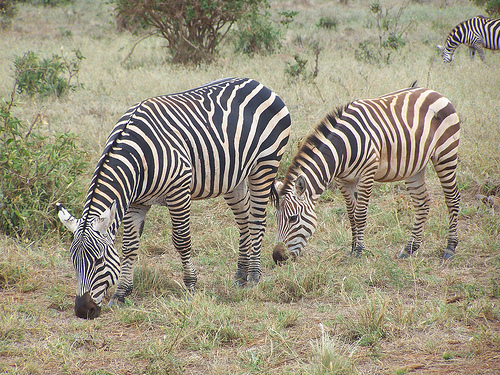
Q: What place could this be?
A: It is a field.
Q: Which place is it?
A: It is a field.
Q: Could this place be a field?
A: Yes, it is a field.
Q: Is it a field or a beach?
A: It is a field.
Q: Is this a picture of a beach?
A: No, the picture is showing a field.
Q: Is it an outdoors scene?
A: Yes, it is outdoors.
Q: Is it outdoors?
A: Yes, it is outdoors.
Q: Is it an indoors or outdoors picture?
A: It is outdoors.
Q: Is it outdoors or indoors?
A: It is outdoors.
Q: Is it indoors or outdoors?
A: It is outdoors.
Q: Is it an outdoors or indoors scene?
A: It is outdoors.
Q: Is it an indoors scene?
A: No, it is outdoors.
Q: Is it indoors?
A: No, it is outdoors.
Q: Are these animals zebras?
A: Yes, all the animals are zebras.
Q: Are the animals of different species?
A: No, all the animals are zebras.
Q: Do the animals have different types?
A: No, all the animals are zebras.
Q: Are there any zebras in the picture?
A: Yes, there are zebras.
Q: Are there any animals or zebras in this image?
A: Yes, there are zebras.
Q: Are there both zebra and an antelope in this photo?
A: No, there are zebras but no antelopes.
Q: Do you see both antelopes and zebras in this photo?
A: No, there are zebras but no antelopes.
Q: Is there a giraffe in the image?
A: No, there are no giraffes.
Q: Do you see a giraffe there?
A: No, there are no giraffes.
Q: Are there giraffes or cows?
A: No, there are no giraffes or cows.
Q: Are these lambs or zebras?
A: These are zebras.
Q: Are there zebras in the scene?
A: Yes, there is a zebra.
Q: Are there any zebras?
A: Yes, there is a zebra.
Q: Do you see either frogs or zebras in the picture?
A: Yes, there is a zebra.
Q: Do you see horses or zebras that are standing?
A: Yes, the zebra is standing.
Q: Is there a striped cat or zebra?
A: Yes, there is a striped zebra.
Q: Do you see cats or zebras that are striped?
A: Yes, the zebra is striped.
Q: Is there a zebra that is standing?
A: Yes, there is a zebra that is standing.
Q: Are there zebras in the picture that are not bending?
A: Yes, there is a zebra that is standing.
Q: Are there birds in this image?
A: No, there are no birds.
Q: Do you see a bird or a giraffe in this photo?
A: No, there are no birds or giraffes.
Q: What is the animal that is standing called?
A: The animal is a zebra.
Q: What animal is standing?
A: The animal is a zebra.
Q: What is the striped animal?
A: The animal is a zebra.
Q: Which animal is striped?
A: The animal is a zebra.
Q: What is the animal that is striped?
A: The animal is a zebra.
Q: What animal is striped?
A: The animal is a zebra.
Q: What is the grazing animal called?
A: The animal is a zebra.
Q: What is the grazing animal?
A: The animal is a zebra.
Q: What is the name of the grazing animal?
A: The animal is a zebra.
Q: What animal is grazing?
A: The animal is a zebra.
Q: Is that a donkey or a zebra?
A: That is a zebra.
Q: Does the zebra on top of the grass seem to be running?
A: No, the zebra is standing.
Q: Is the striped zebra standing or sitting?
A: The zebra is standing.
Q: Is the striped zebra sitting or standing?
A: The zebra is standing.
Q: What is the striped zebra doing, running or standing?
A: The zebra is standing.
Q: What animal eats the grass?
A: The animal is a zebra.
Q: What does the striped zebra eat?
A: The zebra eats grass.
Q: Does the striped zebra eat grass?
A: Yes, the zebra eats grass.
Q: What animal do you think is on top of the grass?
A: The zebra is on top of the grass.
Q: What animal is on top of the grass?
A: The zebra is on top of the grass.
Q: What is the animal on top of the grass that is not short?
A: The animal is a zebra.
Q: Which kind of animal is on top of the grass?
A: The animal is a zebra.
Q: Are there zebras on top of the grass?
A: Yes, there is a zebra on top of the grass.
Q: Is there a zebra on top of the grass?
A: Yes, there is a zebra on top of the grass.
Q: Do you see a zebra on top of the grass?
A: Yes, there is a zebra on top of the grass.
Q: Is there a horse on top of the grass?
A: No, there is a zebra on top of the grass.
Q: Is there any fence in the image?
A: No, there are no fences.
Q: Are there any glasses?
A: No, there are no glasses.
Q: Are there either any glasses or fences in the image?
A: No, there are no glasses or fences.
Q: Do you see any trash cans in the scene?
A: No, there are no trash cans.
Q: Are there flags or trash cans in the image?
A: No, there are no trash cans or flags.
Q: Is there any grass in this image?
A: Yes, there is grass.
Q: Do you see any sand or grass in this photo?
A: Yes, there is grass.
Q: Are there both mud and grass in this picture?
A: No, there is grass but no mud.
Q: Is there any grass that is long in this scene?
A: Yes, there is long grass.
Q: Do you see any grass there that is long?
A: Yes, there is grass that is long.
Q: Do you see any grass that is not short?
A: Yes, there is long grass.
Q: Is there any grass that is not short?
A: Yes, there is long grass.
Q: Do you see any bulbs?
A: No, there are no bulbs.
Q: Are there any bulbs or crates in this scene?
A: No, there are no bulbs or crates.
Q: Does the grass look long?
A: Yes, the grass is long.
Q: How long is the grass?
A: The grass is long.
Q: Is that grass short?
A: No, the grass is long.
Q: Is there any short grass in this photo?
A: No, there is grass but it is long.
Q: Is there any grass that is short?
A: No, there is grass but it is long.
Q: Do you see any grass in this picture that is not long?
A: No, there is grass but it is long.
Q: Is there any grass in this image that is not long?
A: No, there is grass but it is long.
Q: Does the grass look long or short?
A: The grass is long.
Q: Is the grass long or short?
A: The grass is long.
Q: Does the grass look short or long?
A: The grass is long.